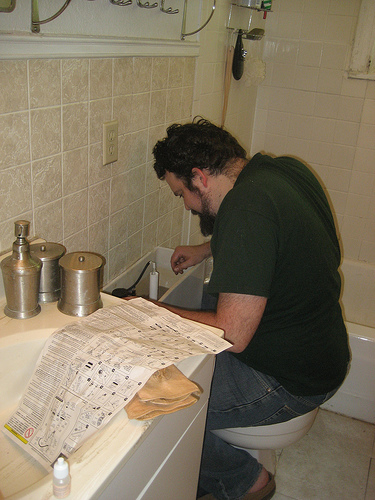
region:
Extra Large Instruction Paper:
[37, 282, 239, 457]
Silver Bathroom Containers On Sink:
[6, 225, 106, 317]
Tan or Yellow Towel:
[107, 362, 209, 432]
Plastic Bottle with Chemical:
[47, 456, 81, 498]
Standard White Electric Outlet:
[81, 116, 141, 178]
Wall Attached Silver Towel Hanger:
[13, 2, 217, 40]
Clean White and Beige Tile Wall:
[1, 59, 194, 135]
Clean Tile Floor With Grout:
[269, 414, 374, 497]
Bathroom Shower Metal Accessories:
[225, 4, 289, 97]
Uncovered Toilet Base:
[97, 250, 219, 288]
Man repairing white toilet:
[152, 116, 350, 497]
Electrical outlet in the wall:
[98, 118, 120, 166]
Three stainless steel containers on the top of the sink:
[3, 218, 104, 314]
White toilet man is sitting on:
[212, 411, 309, 449]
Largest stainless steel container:
[60, 251, 105, 315]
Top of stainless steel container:
[57, 250, 107, 271]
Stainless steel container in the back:
[27, 240, 63, 301]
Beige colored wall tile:
[3, 59, 184, 292]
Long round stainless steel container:
[4, 218, 39, 316]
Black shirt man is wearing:
[209, 152, 347, 343]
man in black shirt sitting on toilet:
[157, 110, 365, 416]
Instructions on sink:
[3, 287, 231, 471]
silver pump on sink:
[4, 216, 107, 316]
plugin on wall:
[102, 114, 123, 167]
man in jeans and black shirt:
[146, 113, 356, 492]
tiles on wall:
[4, 57, 98, 227]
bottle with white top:
[48, 455, 74, 495]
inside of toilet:
[115, 256, 174, 305]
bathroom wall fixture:
[1, 5, 220, 32]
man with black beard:
[149, 114, 353, 416]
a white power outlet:
[71, 107, 135, 175]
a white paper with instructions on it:
[6, 274, 229, 467]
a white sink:
[10, 281, 264, 498]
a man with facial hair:
[137, 110, 259, 229]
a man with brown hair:
[124, 110, 259, 231]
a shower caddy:
[211, 0, 286, 116]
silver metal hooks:
[9, 0, 228, 48]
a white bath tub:
[291, 232, 374, 497]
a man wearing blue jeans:
[156, 46, 329, 464]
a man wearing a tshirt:
[146, 119, 338, 401]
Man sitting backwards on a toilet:
[99, 114, 351, 497]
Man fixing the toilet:
[102, 118, 351, 499]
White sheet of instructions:
[2, 296, 232, 472]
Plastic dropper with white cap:
[51, 455, 73, 499]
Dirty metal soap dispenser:
[0, 218, 41, 320]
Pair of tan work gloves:
[123, 362, 201, 420]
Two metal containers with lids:
[27, 242, 105, 316]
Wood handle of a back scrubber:
[220, 41, 235, 133]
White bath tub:
[196, 237, 374, 425]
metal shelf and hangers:
[27, 1, 218, 39]